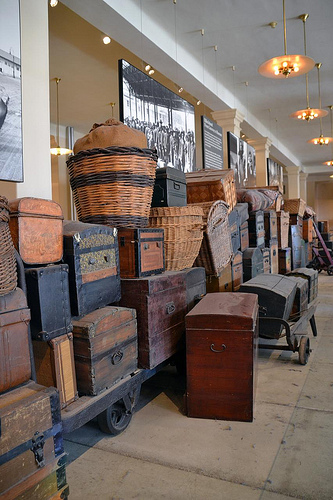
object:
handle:
[210, 343, 225, 353]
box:
[70, 306, 137, 397]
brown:
[213, 312, 227, 315]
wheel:
[298, 335, 313, 365]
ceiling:
[217, 66, 232, 85]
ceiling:
[245, 88, 264, 114]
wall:
[249, 171, 257, 180]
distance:
[285, 205, 323, 340]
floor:
[95, 430, 139, 466]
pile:
[14, 151, 313, 459]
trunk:
[64, 212, 122, 309]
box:
[184, 291, 260, 423]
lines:
[218, 465, 293, 498]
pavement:
[98, 458, 127, 497]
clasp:
[29, 428, 46, 470]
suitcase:
[34, 328, 80, 407]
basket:
[195, 195, 234, 280]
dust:
[204, 297, 227, 312]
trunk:
[0, 379, 73, 498]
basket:
[65, 145, 158, 230]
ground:
[284, 411, 330, 497]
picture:
[0, 0, 24, 182]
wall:
[2, 1, 54, 197]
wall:
[47, 0, 217, 173]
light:
[308, 136, 330, 147]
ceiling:
[201, 3, 251, 31]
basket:
[148, 205, 203, 269]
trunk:
[242, 273, 297, 338]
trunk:
[280, 273, 309, 315]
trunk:
[286, 267, 318, 302]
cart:
[255, 304, 319, 362]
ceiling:
[240, 34, 259, 61]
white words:
[204, 119, 227, 168]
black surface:
[216, 122, 223, 134]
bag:
[73, 118, 147, 156]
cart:
[55, 364, 180, 435]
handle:
[187, 220, 206, 232]